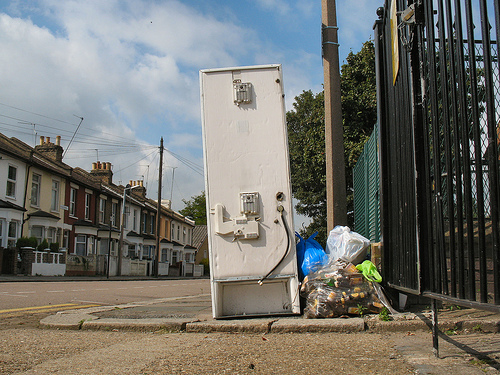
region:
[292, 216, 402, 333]
bags of trash on the sidewalk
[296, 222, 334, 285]
blue trash bag over other bags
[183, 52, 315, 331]
an electrical control box on sidewalk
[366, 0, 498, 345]
a black fence of metal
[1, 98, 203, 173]
electrical wires tend over homes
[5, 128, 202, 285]
homes of different colors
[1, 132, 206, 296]
homes have two floors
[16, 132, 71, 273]
a yellow home with a porch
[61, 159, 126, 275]
two red homes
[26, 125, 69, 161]
a chimney on top a home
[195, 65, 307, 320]
The back of a refrigerator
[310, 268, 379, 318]
Beer bottles in a trash bag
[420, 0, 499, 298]
Black steel gate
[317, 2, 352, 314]
Concrete utility pole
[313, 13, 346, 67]
Sign strapped to concrete utility pole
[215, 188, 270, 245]
Electronic controls for the refrigerator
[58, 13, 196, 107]
White clouds in a blue sky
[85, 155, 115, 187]
Chimney poking out of the roof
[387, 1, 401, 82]
Sign attached to black gate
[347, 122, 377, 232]
Green chain-link fence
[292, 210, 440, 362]
trash on the street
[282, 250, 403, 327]
trash on the street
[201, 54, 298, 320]
back of white appliance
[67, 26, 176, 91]
white clouds in daytime sky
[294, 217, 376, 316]
plastic bags on sidewalk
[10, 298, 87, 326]
yellow lines in street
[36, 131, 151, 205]
chimneys on house roofs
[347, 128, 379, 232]
green chain link fence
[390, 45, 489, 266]
metal poles on fence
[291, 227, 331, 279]
blue trash bag on pile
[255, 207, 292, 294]
black cord on appliance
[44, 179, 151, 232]
windows on front of townhouses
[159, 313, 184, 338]
edge of a road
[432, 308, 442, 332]
part of a metal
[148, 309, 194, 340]
edge of a road